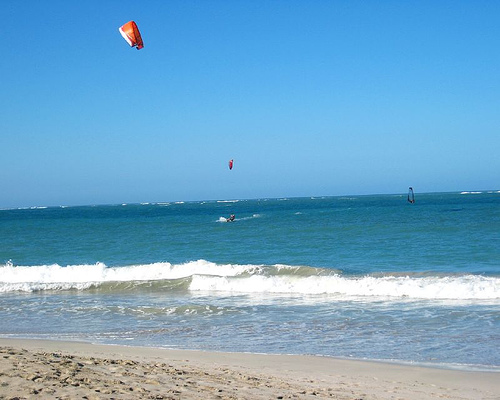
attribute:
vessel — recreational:
[404, 187, 415, 203]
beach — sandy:
[1, 284, 494, 395]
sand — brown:
[23, 356, 109, 398]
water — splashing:
[7, 258, 113, 325]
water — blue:
[18, 219, 181, 256]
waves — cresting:
[3, 256, 498, 321]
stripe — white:
[115, 25, 133, 45]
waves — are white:
[6, 250, 483, 317]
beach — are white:
[6, 325, 466, 393]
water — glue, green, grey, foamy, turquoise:
[1, 179, 498, 369]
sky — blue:
[149, 2, 475, 139]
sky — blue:
[147, 51, 471, 205]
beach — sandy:
[8, 328, 477, 398]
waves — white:
[2, 251, 497, 341]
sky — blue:
[0, 0, 499, 210]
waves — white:
[8, 257, 499, 311]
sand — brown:
[44, 349, 85, 384]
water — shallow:
[388, 300, 481, 321]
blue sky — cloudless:
[194, 17, 459, 142]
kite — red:
[119, 20, 144, 51]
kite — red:
[227, 158, 235, 172]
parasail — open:
[119, 19, 147, 52]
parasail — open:
[225, 157, 236, 172]